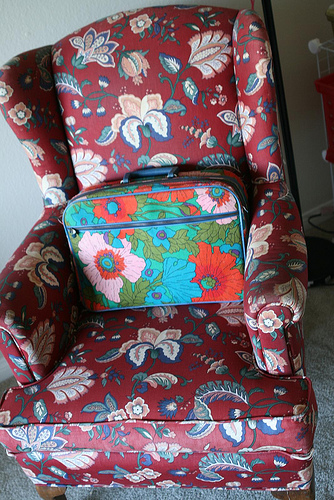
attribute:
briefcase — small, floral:
[68, 168, 266, 315]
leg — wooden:
[272, 478, 317, 498]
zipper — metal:
[229, 195, 258, 225]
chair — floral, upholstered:
[41, 155, 304, 485]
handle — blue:
[118, 156, 192, 189]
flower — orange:
[171, 241, 250, 353]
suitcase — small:
[23, 126, 269, 330]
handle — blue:
[122, 165, 180, 184]